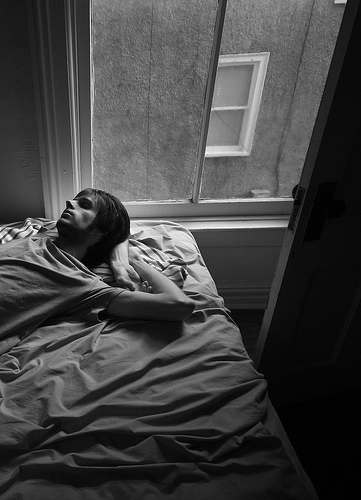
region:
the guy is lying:
[14, 156, 245, 392]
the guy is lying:
[38, 149, 176, 322]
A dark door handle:
[303, 180, 350, 241]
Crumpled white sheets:
[7, 335, 274, 480]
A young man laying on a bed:
[0, 179, 204, 329]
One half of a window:
[207, 50, 271, 157]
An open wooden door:
[258, 44, 359, 386]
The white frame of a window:
[34, 0, 93, 176]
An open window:
[93, 0, 348, 204]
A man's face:
[51, 185, 131, 261]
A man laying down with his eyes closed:
[52, 183, 127, 263]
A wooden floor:
[232, 304, 262, 348]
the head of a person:
[54, 185, 134, 258]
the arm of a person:
[98, 241, 198, 323]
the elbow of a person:
[179, 290, 200, 317]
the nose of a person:
[62, 196, 80, 214]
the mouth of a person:
[60, 205, 75, 216]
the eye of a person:
[76, 195, 94, 209]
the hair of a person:
[73, 182, 132, 251]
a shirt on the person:
[0, 219, 129, 345]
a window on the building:
[199, 47, 272, 162]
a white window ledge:
[174, 212, 303, 235]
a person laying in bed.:
[0, 183, 195, 324]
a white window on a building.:
[200, 48, 273, 165]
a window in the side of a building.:
[71, 3, 348, 197]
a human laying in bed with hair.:
[53, 182, 140, 255]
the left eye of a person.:
[72, 196, 96, 213]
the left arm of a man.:
[77, 246, 199, 334]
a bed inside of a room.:
[0, 212, 311, 484]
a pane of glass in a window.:
[91, 2, 219, 204]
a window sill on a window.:
[49, 190, 298, 237]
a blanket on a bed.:
[2, 292, 234, 481]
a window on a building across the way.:
[203, 46, 275, 158]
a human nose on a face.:
[64, 198, 78, 210]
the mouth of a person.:
[59, 209, 77, 222]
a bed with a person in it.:
[0, 221, 313, 495]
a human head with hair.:
[50, 169, 142, 252]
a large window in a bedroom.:
[85, 1, 343, 205]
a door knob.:
[278, 176, 318, 236]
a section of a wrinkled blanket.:
[86, 343, 206, 431]